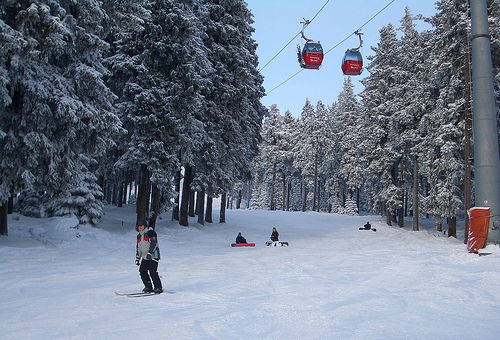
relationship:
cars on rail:
[295, 30, 423, 110] [272, 12, 419, 86]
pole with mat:
[444, 47, 484, 153] [452, 192, 482, 246]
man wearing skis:
[108, 200, 203, 328] [108, 265, 177, 313]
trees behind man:
[17, 46, 202, 156] [134, 220, 164, 293]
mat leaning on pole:
[445, 196, 483, 264] [464, 69, 484, 139]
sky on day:
[259, 25, 295, 81] [280, 71, 340, 136]